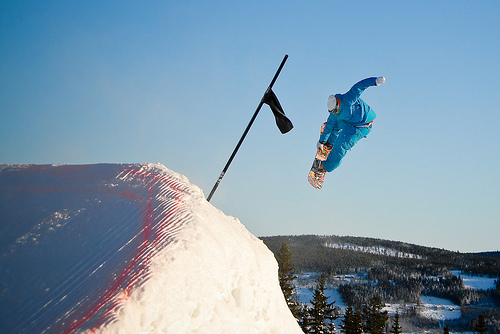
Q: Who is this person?
A: A snowboarder.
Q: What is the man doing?
A: Snowboarding.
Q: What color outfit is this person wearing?
A: Blue.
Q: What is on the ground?
A: Snow.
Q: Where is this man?
A: In the air.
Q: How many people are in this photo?
A: One.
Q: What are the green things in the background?
A: Trees.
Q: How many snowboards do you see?
A: 1.